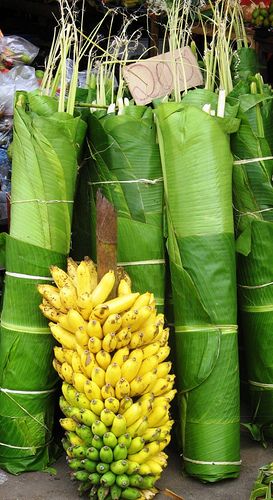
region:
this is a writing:
[144, 60, 182, 93]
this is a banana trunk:
[78, 288, 152, 481]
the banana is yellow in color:
[111, 370, 119, 374]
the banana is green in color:
[73, 442, 95, 456]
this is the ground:
[15, 481, 55, 489]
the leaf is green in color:
[194, 359, 220, 402]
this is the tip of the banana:
[123, 433, 133, 436]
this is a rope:
[120, 177, 152, 188]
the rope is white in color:
[205, 452, 226, 466]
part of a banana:
[143, 458, 152, 472]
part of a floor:
[179, 473, 194, 490]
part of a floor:
[45, 483, 57, 491]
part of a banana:
[144, 468, 154, 489]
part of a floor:
[186, 483, 192, 494]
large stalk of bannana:
[35, 250, 178, 498]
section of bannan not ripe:
[60, 431, 139, 499]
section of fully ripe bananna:
[34, 252, 181, 403]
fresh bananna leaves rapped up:
[1, 88, 59, 474]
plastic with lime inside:
[0, 36, 38, 64]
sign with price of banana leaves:
[120, 48, 196, 106]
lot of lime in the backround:
[248, 2, 270, 23]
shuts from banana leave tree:
[45, 0, 232, 115]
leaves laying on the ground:
[247, 460, 271, 499]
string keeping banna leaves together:
[86, 178, 164, 182]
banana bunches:
[41, 247, 168, 494]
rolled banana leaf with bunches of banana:
[20, 204, 271, 468]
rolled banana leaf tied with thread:
[78, 175, 177, 192]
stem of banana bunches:
[93, 190, 128, 261]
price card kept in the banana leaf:
[116, 51, 209, 103]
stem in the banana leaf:
[251, 81, 257, 86]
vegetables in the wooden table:
[194, 2, 270, 26]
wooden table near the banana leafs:
[149, 13, 260, 64]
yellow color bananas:
[59, 273, 138, 367]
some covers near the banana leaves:
[1, 37, 72, 96]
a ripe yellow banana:
[74, 257, 88, 291]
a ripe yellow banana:
[87, 266, 108, 305]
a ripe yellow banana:
[104, 292, 139, 310]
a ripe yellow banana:
[44, 260, 74, 291]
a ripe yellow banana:
[64, 253, 75, 279]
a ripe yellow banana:
[66, 304, 85, 329]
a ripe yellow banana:
[86, 317, 100, 336]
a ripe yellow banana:
[99, 330, 114, 350]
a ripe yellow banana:
[117, 324, 130, 342]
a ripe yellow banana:
[131, 331, 143, 348]